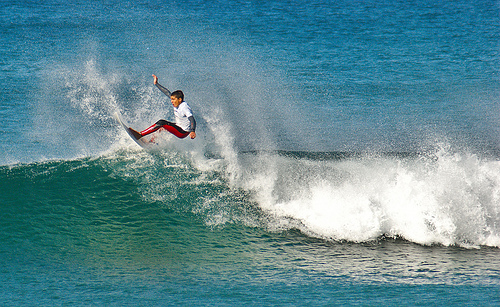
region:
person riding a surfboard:
[110, 71, 200, 154]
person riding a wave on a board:
[110, 71, 206, 156]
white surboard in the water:
[110, 110, 158, 154]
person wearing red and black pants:
[115, 66, 207, 159]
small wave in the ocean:
[2, 143, 498, 260]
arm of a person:
[150, 73, 170, 104]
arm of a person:
[186, 108, 198, 146]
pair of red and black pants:
[132, 114, 189, 148]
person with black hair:
[111, 69, 203, 155]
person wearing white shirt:
[111, 71, 199, 156]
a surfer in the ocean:
[10, 11, 495, 283]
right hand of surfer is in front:
[123, 63, 200, 152]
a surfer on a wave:
[11, 67, 481, 233]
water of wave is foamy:
[260, 150, 498, 255]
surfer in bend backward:
[116, 55, 202, 151]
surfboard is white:
[107, 105, 162, 167]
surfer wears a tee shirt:
[120, 62, 202, 159]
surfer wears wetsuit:
[120, 57, 203, 153]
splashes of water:
[26, 6, 483, 162]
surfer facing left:
[97, 63, 222, 171]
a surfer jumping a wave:
[51, 32, 228, 175]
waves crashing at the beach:
[232, 124, 498, 274]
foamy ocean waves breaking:
[250, 113, 492, 288]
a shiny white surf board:
[110, 113, 163, 162]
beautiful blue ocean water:
[243, 2, 492, 121]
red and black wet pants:
[118, 120, 193, 159]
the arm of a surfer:
[148, 68, 170, 105]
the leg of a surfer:
[130, 115, 189, 141]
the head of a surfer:
[167, 89, 188, 106]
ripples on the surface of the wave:
[7, 194, 204, 276]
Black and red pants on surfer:
[123, 118, 195, 142]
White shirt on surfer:
[168, 101, 201, 138]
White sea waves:
[65, 65, 498, 250]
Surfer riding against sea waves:
[113, 72, 198, 153]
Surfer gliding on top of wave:
[125, 72, 195, 154]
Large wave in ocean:
[2, 146, 494, 304]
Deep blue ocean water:
[1, 3, 496, 145]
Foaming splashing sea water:
[276, 163, 498, 234]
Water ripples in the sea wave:
[8, 171, 498, 301]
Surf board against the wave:
[123, 124, 175, 159]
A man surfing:
[105, 64, 212, 171]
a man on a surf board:
[114, 69, 223, 151]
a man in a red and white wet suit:
[138, 78, 212, 150]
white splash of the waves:
[267, 141, 499, 257]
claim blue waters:
[234, 9, 496, 71]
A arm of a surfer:
[139, 65, 197, 99]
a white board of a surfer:
[112, 111, 154, 155]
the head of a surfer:
[166, 86, 196, 112]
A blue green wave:
[15, 149, 489, 270]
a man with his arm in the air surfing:
[105, 73, 222, 173]